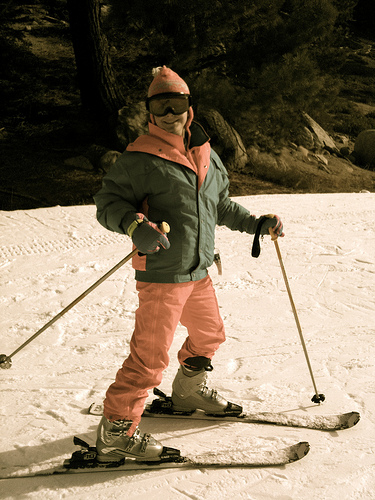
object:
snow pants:
[102, 275, 225, 438]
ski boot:
[95, 415, 180, 465]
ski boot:
[171, 362, 242, 416]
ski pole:
[267, 226, 324, 406]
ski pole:
[0, 220, 171, 369]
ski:
[87, 400, 360, 431]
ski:
[1, 440, 310, 478]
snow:
[247, 410, 338, 429]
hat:
[146, 64, 194, 151]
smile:
[157, 115, 183, 129]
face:
[153, 96, 187, 134]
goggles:
[146, 91, 193, 117]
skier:
[93, 64, 285, 466]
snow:
[0, 191, 374, 498]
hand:
[256, 214, 285, 238]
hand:
[131, 217, 171, 255]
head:
[144, 65, 191, 139]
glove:
[121, 209, 171, 254]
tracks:
[1, 235, 131, 263]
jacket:
[93, 120, 255, 284]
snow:
[188, 447, 288, 466]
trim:
[125, 119, 210, 191]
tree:
[40, 1, 128, 116]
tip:
[329, 410, 360, 431]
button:
[157, 147, 163, 152]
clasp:
[139, 431, 151, 454]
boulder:
[285, 108, 343, 157]